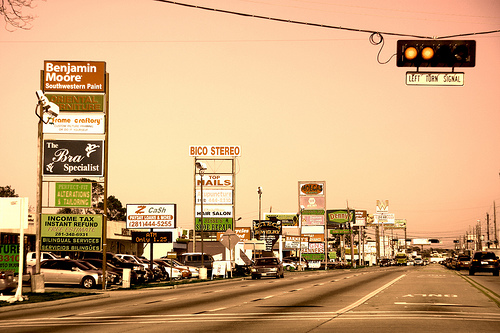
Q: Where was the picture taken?
A: On a street.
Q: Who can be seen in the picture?
A: No one.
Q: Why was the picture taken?
A: To capture the street.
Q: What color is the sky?
A: Red.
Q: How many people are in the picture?
A: None.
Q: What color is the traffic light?
A: Red.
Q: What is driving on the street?
A: Motor vehicles.